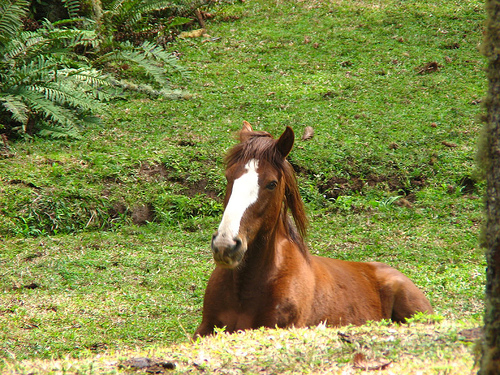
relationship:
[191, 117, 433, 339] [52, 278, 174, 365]
horse in grass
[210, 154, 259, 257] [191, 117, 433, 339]
spot on horse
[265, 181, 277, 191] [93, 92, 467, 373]
eye on horse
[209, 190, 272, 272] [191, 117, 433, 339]
nose on horse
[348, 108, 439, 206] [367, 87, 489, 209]
spot in grass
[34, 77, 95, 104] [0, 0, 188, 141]
leaves on ferns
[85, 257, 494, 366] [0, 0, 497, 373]
ditch on field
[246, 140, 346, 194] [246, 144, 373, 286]
mane on horse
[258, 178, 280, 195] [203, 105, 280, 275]
eye on head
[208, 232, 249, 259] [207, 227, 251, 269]
nostrils on nose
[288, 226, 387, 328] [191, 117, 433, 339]
torso on horse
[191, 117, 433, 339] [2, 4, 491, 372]
horse sitting on grass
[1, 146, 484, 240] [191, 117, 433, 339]
ditch behind horse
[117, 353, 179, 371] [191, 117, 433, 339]
rock in front of horse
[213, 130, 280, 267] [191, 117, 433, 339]
face on horse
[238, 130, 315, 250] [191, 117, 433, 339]
mane on horse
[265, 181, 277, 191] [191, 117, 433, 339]
eye on horse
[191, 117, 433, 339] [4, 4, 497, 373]
horse lying on field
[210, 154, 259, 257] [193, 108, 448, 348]
spot on horse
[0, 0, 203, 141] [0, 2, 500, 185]
ferns on grassy hillside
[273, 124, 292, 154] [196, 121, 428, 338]
ear on horse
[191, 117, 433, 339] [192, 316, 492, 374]
horse casting shadow